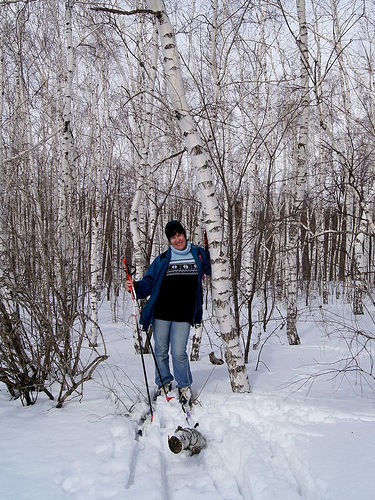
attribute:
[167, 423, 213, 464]
tree — split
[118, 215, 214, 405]
woman — standing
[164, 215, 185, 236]
hair — black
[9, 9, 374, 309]
trees — leafless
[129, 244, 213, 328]
coat — blue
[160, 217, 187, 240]
hair — dark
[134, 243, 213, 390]
clothing — blue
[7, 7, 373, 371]
trees — leafless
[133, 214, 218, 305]
woman — smiling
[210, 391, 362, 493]
snow — white